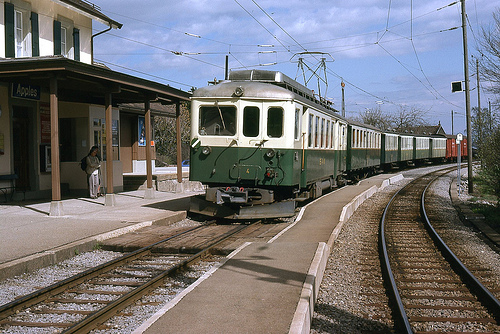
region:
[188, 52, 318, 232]
train on the train tracks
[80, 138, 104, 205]
person standing in the train station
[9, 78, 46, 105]
sign on the train station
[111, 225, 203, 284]
shadow on the train tracks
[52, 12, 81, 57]
window on the train station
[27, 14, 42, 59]
shutter on the train station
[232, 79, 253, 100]
light on the train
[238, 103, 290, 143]
windows on the train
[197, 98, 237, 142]
window on the train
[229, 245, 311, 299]
shadow on the pavement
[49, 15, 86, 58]
Small window on a building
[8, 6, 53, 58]
Small window on a building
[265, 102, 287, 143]
Small window on a train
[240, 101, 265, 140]
Small window on a train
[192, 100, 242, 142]
Small window on a train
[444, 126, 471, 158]
Red train cart on the tracks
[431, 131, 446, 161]
Green and white train cart on tracks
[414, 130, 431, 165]
Green and white train cart on tracks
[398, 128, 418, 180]
Green and white train cart on tracks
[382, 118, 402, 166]
Green and white train cart on tracks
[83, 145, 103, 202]
a person is standing in the shade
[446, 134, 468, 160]
a red car on the train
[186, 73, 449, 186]
the train is green and white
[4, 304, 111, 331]
wood boards under the tracks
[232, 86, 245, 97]
round light on the train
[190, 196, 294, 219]
large bumper on the train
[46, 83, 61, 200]
a wood support post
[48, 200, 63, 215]
concrete base for the post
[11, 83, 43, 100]
a business sign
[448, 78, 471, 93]
a sign on the post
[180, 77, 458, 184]
the train is moving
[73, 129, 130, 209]
twopeople standing waiting for train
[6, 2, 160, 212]
building next to the train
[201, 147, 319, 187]
the base of the train is green in color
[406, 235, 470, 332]
the rail way is full of rocks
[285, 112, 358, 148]
the upper of the train is white in color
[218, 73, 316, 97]
the upper side is silvery in color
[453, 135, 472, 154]
the container is red in color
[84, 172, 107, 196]
pants are grey in color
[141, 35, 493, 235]
commuter train at station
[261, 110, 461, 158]
row of windows on train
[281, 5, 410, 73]
white clouds in blue sky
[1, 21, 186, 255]
train station on left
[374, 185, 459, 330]
second set of tracks on right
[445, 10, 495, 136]
tall wooden electrical pole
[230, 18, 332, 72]
electric lines hanging over train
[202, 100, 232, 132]
windshield wiper on train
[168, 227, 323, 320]
shadow crossing train tracks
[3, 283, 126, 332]
train tracks on gravel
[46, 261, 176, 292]
train tracks on gravel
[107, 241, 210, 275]
train tracks on gravel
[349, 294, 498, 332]
train tracks on gravel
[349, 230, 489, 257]
train tracks on gravel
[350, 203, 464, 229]
train tracks on gravel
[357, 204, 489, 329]
train tracks on gravel